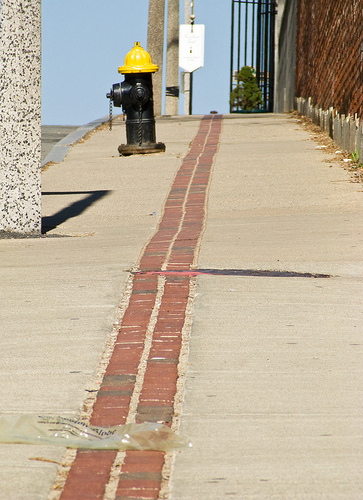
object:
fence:
[228, 0, 277, 113]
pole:
[189, 72, 192, 115]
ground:
[235, 128, 281, 211]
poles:
[177, 0, 205, 115]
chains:
[137, 103, 144, 146]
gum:
[205, 475, 230, 486]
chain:
[109, 93, 114, 131]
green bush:
[230, 65, 264, 112]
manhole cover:
[129, 261, 333, 281]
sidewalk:
[0, 112, 363, 499]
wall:
[293, 1, 362, 156]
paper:
[2, 410, 191, 455]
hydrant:
[105, 40, 168, 155]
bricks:
[155, 112, 223, 245]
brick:
[114, 487, 160, 498]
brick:
[119, 450, 164, 489]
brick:
[71, 451, 112, 498]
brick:
[85, 408, 124, 449]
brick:
[138, 362, 181, 400]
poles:
[0, 0, 45, 240]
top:
[116, 40, 158, 75]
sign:
[176, 22, 205, 73]